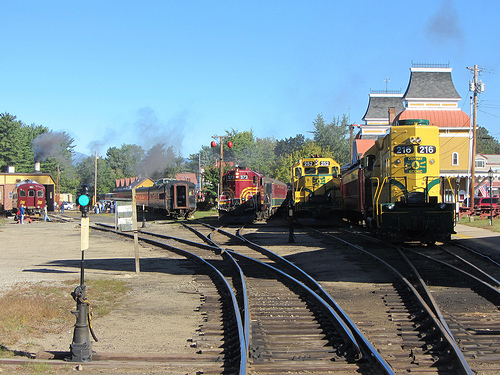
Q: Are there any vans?
A: No, there are no vans.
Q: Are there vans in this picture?
A: No, there are no vans.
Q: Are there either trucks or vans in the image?
A: No, there are no vans or trucks.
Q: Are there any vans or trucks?
A: No, there are no vans or trucks.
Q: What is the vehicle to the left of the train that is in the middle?
A: The vehicle is a car.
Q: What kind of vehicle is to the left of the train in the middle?
A: The vehicle is a car.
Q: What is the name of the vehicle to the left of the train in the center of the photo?
A: The vehicle is a car.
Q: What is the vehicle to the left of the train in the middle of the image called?
A: The vehicle is a car.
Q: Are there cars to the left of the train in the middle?
A: Yes, there is a car to the left of the train.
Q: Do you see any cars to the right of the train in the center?
A: No, the car is to the left of the train.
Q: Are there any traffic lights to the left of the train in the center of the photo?
A: No, there is a car to the left of the train.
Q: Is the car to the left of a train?
A: Yes, the car is to the left of a train.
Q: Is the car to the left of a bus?
A: No, the car is to the left of a train.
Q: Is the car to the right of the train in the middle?
A: No, the car is to the left of the train.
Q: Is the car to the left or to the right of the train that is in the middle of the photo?
A: The car is to the left of the train.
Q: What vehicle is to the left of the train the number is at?
A: The vehicle is a car.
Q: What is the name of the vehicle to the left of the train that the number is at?
A: The vehicle is a car.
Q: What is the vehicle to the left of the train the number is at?
A: The vehicle is a car.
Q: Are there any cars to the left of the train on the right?
A: Yes, there is a car to the left of the train.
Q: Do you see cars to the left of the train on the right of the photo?
A: Yes, there is a car to the left of the train.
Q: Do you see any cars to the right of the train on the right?
A: No, the car is to the left of the train.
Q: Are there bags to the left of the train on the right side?
A: No, there is a car to the left of the train.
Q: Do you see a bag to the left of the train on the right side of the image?
A: No, there is a car to the left of the train.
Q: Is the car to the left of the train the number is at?
A: Yes, the car is to the left of the train.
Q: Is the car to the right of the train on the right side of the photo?
A: No, the car is to the left of the train.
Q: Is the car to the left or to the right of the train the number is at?
A: The car is to the left of the train.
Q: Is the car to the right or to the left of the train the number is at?
A: The car is to the left of the train.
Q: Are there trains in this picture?
A: Yes, there is a train.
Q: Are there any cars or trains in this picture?
A: Yes, there is a train.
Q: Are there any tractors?
A: No, there are no tractors.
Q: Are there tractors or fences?
A: No, there are no tractors or fences.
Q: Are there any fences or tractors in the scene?
A: No, there are no tractors or fences.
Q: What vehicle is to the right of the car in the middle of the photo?
A: The vehicle is a train.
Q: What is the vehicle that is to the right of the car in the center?
A: The vehicle is a train.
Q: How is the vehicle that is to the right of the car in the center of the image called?
A: The vehicle is a train.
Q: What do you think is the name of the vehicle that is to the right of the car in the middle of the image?
A: The vehicle is a train.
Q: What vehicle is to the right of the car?
A: The vehicle is a train.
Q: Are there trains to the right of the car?
A: Yes, there is a train to the right of the car.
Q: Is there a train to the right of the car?
A: Yes, there is a train to the right of the car.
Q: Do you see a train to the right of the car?
A: Yes, there is a train to the right of the car.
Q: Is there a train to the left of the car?
A: No, the train is to the right of the car.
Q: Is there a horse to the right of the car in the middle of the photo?
A: No, there is a train to the right of the car.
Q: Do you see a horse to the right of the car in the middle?
A: No, there is a train to the right of the car.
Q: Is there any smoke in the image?
A: Yes, there is smoke.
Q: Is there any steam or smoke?
A: Yes, there is smoke.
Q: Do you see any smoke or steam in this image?
A: Yes, there is smoke.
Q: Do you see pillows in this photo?
A: No, there are no pillows.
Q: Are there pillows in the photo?
A: No, there are no pillows.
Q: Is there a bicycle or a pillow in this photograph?
A: No, there are no pillows or bicycles.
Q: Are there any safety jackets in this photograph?
A: No, there are no safety jackets.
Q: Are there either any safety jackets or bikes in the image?
A: No, there are no safety jackets or bikes.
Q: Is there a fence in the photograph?
A: No, there are no fences.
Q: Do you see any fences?
A: No, there are no fences.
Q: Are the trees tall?
A: Yes, the trees are tall.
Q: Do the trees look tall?
A: Yes, the trees are tall.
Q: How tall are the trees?
A: The trees are tall.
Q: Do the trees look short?
A: No, the trees are tall.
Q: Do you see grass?
A: Yes, there is grass.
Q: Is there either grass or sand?
A: Yes, there is grass.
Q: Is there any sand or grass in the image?
A: Yes, there is grass.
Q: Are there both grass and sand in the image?
A: No, there is grass but no sand.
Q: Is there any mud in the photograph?
A: No, there is no mud.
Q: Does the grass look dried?
A: Yes, the grass is dried.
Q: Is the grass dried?
A: Yes, the grass is dried.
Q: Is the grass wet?
A: No, the grass is dried.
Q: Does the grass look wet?
A: No, the grass is dried.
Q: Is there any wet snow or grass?
A: No, there is grass but it is dried.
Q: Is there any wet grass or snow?
A: No, there is grass but it is dried.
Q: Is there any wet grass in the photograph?
A: No, there is grass but it is dried.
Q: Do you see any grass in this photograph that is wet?
A: No, there is grass but it is dried.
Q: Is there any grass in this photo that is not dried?
A: No, there is grass but it is dried.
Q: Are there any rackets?
A: No, there are no rackets.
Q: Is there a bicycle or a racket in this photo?
A: No, there are no rackets or bicycles.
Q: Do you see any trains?
A: Yes, there is a train.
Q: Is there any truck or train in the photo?
A: Yes, there is a train.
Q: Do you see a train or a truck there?
A: Yes, there is a train.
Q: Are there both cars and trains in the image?
A: Yes, there are both a train and cars.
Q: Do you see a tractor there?
A: No, there are no tractors.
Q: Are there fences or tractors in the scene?
A: No, there are no tractors or fences.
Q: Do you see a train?
A: Yes, there is a train.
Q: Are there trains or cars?
A: Yes, there is a train.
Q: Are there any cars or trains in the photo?
A: Yes, there is a train.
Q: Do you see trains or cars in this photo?
A: Yes, there is a train.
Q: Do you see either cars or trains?
A: Yes, there is a train.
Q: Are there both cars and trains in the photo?
A: Yes, there are both a train and a car.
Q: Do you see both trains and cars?
A: Yes, there are both a train and a car.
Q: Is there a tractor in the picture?
A: No, there are no tractors.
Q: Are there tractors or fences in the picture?
A: No, there are no tractors or fences.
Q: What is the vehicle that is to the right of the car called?
A: The vehicle is a train.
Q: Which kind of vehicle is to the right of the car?
A: The vehicle is a train.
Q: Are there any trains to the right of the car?
A: Yes, there is a train to the right of the car.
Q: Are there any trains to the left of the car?
A: No, the train is to the right of the car.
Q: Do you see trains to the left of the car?
A: No, the train is to the right of the car.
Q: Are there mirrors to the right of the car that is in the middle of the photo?
A: No, there is a train to the right of the car.